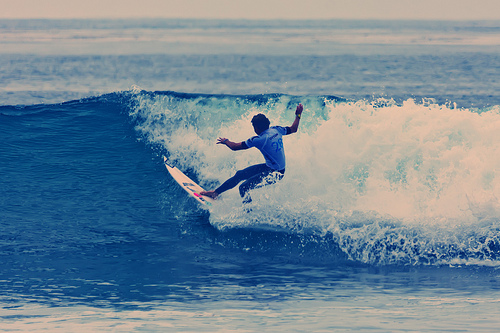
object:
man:
[197, 105, 303, 216]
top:
[243, 125, 290, 171]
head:
[251, 114, 272, 132]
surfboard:
[161, 153, 214, 207]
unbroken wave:
[1, 85, 139, 111]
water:
[2, 19, 499, 331]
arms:
[278, 101, 311, 136]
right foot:
[197, 189, 221, 202]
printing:
[180, 182, 200, 196]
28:
[268, 139, 286, 156]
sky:
[3, 0, 498, 24]